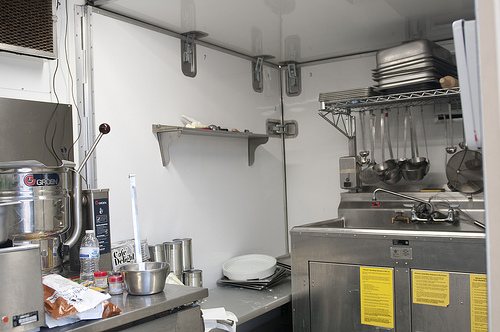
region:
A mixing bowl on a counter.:
[8, 138, 110, 268]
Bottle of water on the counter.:
[64, 222, 106, 278]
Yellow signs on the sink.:
[326, 260, 496, 327]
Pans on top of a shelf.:
[356, 34, 440, 88]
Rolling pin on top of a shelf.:
[433, 65, 456, 93]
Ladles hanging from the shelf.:
[336, 105, 481, 182]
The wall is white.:
[163, 172, 255, 217]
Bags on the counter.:
[42, 263, 120, 328]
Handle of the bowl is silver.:
[61, 110, 121, 175]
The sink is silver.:
[283, 230, 356, 330]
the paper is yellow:
[333, 270, 410, 328]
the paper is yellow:
[359, 245, 383, 326]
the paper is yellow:
[363, 260, 395, 330]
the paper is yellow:
[405, 258, 460, 328]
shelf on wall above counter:
[148, 103, 269, 163]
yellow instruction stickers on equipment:
[350, 263, 485, 327]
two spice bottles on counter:
[90, 265, 127, 295]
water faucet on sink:
[363, 175, 461, 227]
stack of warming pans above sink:
[361, 33, 457, 98]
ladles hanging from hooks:
[347, 115, 442, 192]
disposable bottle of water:
[67, 225, 107, 290]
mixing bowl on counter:
[116, 256, 178, 301]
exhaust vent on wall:
[3, 5, 65, 62]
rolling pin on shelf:
[431, 64, 459, 94]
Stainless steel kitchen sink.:
[293, 177, 499, 287]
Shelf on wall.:
[148, 117, 266, 163]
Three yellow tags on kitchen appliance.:
[319, 250, 499, 330]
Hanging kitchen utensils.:
[358, 108, 443, 186]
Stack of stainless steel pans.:
[354, 36, 436, 88]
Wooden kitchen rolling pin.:
[438, 70, 455, 101]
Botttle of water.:
[75, 223, 100, 278]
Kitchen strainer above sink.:
[438, 141, 490, 199]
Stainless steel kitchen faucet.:
[365, 180, 450, 215]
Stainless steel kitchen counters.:
[130, 248, 288, 328]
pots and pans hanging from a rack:
[321, 92, 478, 219]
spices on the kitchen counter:
[86, 255, 132, 302]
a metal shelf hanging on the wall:
[149, 110, 277, 185]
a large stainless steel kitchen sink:
[306, 170, 486, 325]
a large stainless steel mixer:
[6, 145, 95, 282]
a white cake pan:
[218, 252, 290, 308]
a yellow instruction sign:
[346, 247, 392, 329]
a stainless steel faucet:
[363, 169, 454, 241]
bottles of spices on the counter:
[86, 257, 128, 301]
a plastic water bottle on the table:
[73, 222, 115, 304]